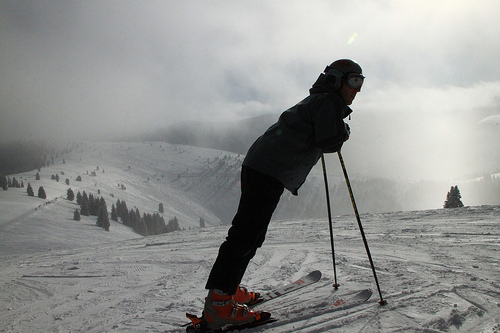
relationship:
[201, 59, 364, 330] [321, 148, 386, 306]
skier leaning on poles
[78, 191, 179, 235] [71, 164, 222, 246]
trees on slope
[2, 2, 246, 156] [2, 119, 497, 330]
mist over a hill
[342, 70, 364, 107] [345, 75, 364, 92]
face has goggles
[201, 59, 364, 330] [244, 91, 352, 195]
skier has coat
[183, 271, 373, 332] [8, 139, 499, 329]
skiis on snow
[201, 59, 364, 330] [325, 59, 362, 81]
skier has a helmet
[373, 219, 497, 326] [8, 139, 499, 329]
marks on snow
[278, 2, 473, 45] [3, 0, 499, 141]
sunlight in sky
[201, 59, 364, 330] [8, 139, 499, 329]
skier in snow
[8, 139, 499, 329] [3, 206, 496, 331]
snow on ground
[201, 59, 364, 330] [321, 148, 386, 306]
skier has poles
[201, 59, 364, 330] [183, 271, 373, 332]
skier has skis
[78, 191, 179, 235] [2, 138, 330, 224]
trees on a hill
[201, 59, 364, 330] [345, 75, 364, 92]
skier has goggles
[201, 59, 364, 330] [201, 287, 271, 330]
man has boots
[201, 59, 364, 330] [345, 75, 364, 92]
skier wearing goggles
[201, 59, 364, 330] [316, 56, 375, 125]
man looking ahead